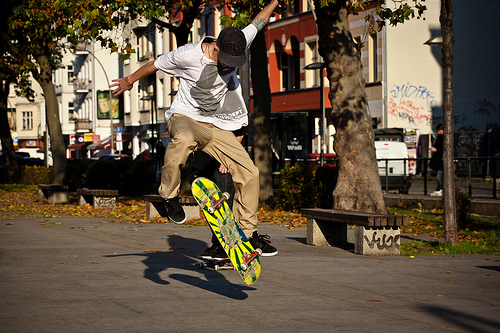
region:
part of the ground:
[318, 253, 420, 323]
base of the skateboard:
[198, 187, 260, 272]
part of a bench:
[326, 197, 388, 248]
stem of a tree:
[332, 87, 369, 196]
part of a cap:
[219, 47, 241, 74]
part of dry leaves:
[48, 197, 112, 227]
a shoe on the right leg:
[160, 191, 185, 228]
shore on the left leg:
[247, 230, 282, 257]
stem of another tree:
[435, 60, 457, 233]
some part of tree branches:
[11, 0, 108, 53]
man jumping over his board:
[97, 18, 330, 281]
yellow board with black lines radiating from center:
[175, 167, 267, 277]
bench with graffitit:
[290, 191, 405, 261]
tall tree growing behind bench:
[307, 47, 408, 267]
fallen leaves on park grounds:
[15, 172, 451, 252]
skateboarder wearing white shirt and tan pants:
[100, 25, 295, 260]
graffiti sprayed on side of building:
[376, 25, 453, 170]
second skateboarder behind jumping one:
[122, 40, 292, 285]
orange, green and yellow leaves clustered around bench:
[30, 175, 155, 220]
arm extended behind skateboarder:
[96, 26, 242, 127]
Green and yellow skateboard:
[182, 167, 280, 288]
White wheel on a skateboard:
[197, 201, 227, 216]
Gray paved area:
[12, 214, 183, 306]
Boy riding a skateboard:
[107, 8, 299, 278]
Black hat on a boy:
[190, 21, 278, 76]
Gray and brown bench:
[286, 207, 404, 258]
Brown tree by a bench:
[305, 60, 400, 226]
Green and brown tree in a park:
[4, 9, 106, 206]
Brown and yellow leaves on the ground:
[5, 185, 224, 235]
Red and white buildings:
[51, 22, 388, 182]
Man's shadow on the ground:
[98, 231, 256, 308]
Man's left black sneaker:
[153, 193, 194, 223]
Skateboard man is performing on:
[191, 175, 277, 290]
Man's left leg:
[216, 129, 277, 236]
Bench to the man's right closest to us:
[295, 203, 407, 257]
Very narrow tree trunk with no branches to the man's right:
[438, 12, 458, 237]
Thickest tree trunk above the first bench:
[313, 10, 390, 206]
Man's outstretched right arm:
[108, 46, 192, 93]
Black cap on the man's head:
[215, 23, 247, 68]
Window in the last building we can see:
[13, 101, 41, 141]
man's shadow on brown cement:
[113, 227, 294, 285]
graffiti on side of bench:
[353, 228, 410, 253]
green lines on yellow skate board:
[190, 164, 222, 200]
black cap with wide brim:
[215, 19, 258, 76]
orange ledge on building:
[269, 85, 349, 125]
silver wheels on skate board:
[200, 184, 246, 221]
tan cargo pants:
[130, 102, 289, 221]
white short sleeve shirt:
[149, 42, 272, 147]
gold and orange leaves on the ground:
[33, 185, 142, 233]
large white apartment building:
[95, 29, 177, 172]